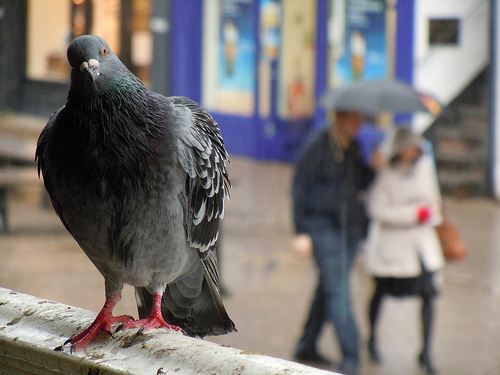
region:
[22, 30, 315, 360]
a pigeon peers into the camera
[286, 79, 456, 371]
a couple holding an umbrella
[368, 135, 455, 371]
a woman wearing a white coat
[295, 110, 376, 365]
a man wearing blue jeans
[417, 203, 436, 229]
red gloves cover a woman's hands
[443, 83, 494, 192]
black and gray steps next to a store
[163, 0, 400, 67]
a blue storefront behind the bird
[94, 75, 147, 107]
green feathers adorning the pigeon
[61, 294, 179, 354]
red feet with black claws support the bird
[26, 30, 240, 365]
a gray pigeon perches on a white railing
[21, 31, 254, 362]
Dove looking to the right side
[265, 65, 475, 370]
Two adults walking in the street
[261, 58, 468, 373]
Two adults walking in the right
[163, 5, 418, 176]
Blue building in the right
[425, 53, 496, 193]
Stairs next to the building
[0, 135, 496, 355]
Road is wet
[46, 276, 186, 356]
Dove has pink feet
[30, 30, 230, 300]
Dove has grey body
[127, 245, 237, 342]
Tail of dove is long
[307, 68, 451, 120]
Umbrella is black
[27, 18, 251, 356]
Dove standing on a edge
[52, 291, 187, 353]
Feet of dove is pink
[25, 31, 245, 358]
Dove has grey body and pink feet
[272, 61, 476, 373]
Two people walking in the street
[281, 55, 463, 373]
A man holding an umbrella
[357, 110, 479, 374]
Woman wears red gloves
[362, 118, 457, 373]
Woman wears white jacket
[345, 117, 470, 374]
Person wears black skirt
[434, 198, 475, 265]
Brown bag holding by a woman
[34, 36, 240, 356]
pigeon perched above a street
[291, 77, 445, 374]
couple walking under an umbrella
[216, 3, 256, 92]
sign in a store window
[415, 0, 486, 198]
stairwell next to a building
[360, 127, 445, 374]
woman carrying a handbag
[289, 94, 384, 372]
man holding an umbrella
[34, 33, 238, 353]
pigeon is black and gray feathered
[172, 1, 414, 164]
dark blue store front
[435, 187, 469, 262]
handbag is large and brown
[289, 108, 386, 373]
man is wearing blue jeans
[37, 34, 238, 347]
a pigeon is in the foreground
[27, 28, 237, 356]
the pigeon is grey in color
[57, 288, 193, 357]
the pigeon has red feet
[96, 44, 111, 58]
the pigeon eye is orange in color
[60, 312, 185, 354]
the pigeon has long claws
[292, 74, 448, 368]
a couple is covered by an umbrella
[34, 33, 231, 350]
the pigeon has fluffy feathers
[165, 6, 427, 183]
the store front is blue in color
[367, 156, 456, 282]
a woman is wearing a white coat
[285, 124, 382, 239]
a man is wearing a black jacket